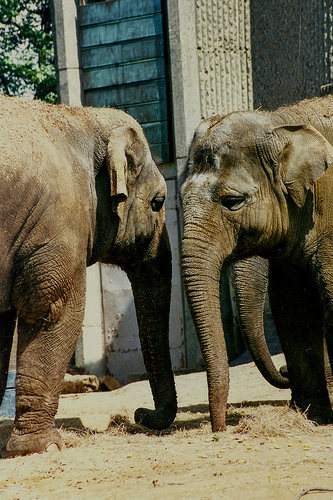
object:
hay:
[230, 406, 317, 437]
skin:
[193, 210, 211, 302]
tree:
[0, 0, 62, 107]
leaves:
[9, 8, 15, 14]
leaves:
[30, 75, 36, 79]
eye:
[220, 192, 250, 214]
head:
[92, 105, 168, 268]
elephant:
[179, 92, 333, 430]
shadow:
[103, 410, 248, 432]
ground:
[0, 318, 333, 500]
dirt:
[0, 353, 333, 497]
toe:
[45, 442, 58, 453]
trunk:
[179, 216, 232, 433]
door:
[75, 0, 187, 387]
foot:
[7, 423, 64, 454]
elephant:
[0, 92, 179, 460]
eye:
[150, 197, 166, 212]